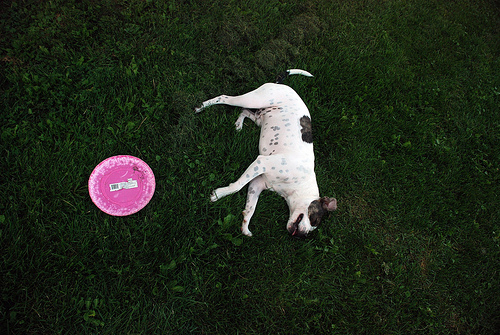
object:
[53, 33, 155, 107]
patch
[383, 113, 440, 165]
patch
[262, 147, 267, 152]
spot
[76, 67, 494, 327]
ground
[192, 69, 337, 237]
dog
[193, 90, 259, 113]
legs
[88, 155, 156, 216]
frisbee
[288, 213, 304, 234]
mouth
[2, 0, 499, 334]
grass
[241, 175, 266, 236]
legs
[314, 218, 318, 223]
closed eye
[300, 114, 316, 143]
spot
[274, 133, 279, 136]
spots